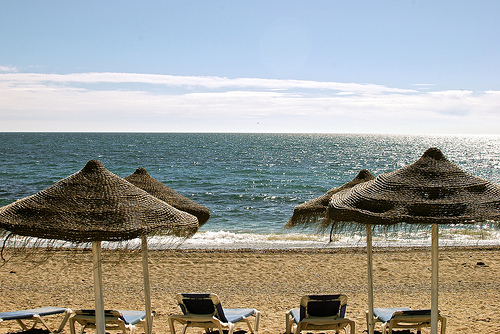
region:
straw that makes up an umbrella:
[372, 162, 414, 228]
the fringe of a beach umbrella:
[363, 209, 412, 243]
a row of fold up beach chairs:
[275, 276, 414, 332]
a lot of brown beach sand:
[220, 243, 317, 295]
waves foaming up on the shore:
[212, 222, 257, 257]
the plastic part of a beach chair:
[302, 299, 340, 326]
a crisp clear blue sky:
[110, 24, 175, 56]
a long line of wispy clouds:
[186, 62, 253, 117]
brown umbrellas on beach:
[15, 152, 482, 289]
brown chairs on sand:
[0, 289, 400, 331]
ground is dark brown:
[207, 261, 307, 302]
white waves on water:
[163, 219, 346, 246]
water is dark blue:
[194, 152, 261, 202]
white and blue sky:
[137, 25, 257, 126]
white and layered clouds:
[132, 30, 229, 119]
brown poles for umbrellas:
[318, 218, 450, 332]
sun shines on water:
[375, 116, 498, 176]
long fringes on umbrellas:
[0, 207, 189, 264]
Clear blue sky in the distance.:
[245, 13, 430, 54]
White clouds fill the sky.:
[78, 88, 403, 131]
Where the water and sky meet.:
[159, 113, 343, 160]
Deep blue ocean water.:
[174, 136, 282, 181]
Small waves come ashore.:
[200, 226, 306, 249]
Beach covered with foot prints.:
[186, 240, 319, 274]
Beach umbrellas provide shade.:
[285, 118, 483, 272]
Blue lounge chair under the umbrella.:
[370, 273, 450, 331]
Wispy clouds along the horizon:
[2, 65, 494, 140]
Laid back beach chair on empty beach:
[66, 300, 152, 329]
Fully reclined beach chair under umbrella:
[367, 300, 442, 330]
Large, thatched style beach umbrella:
[332, 143, 497, 332]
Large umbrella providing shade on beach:
[2, 160, 197, 331]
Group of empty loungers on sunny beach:
[1, 288, 456, 333]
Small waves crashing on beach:
[204, 223, 308, 255]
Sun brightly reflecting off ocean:
[426, 129, 498, 165]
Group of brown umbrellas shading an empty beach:
[1, 143, 496, 248]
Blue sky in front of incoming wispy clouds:
[1, 2, 498, 84]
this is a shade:
[0, 163, 198, 327]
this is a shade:
[117, 159, 212, 331]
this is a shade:
[326, 93, 492, 325]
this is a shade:
[252, 120, 416, 327]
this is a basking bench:
[368, 280, 461, 328]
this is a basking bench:
[280, 282, 371, 331]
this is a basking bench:
[166, 280, 274, 330]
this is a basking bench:
[64, 288, 161, 325]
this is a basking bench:
[6, 288, 94, 327]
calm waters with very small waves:
[31, 138, 57, 167]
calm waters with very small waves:
[57, 133, 92, 160]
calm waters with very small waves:
[141, 131, 188, 175]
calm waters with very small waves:
[246, 132, 294, 199]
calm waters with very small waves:
[301, 132, 351, 186]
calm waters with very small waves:
[366, 135, 411, 181]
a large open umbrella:
[9, 160, 202, 331]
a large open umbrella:
[118, 165, 209, 327]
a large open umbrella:
[296, 156, 388, 332]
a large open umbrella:
[328, 152, 496, 332]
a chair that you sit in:
[369, 294, 436, 331]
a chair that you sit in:
[278, 293, 352, 330]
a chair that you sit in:
[169, 284, 264, 329]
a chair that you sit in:
[76, 291, 156, 331]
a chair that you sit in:
[1, 297, 72, 332]